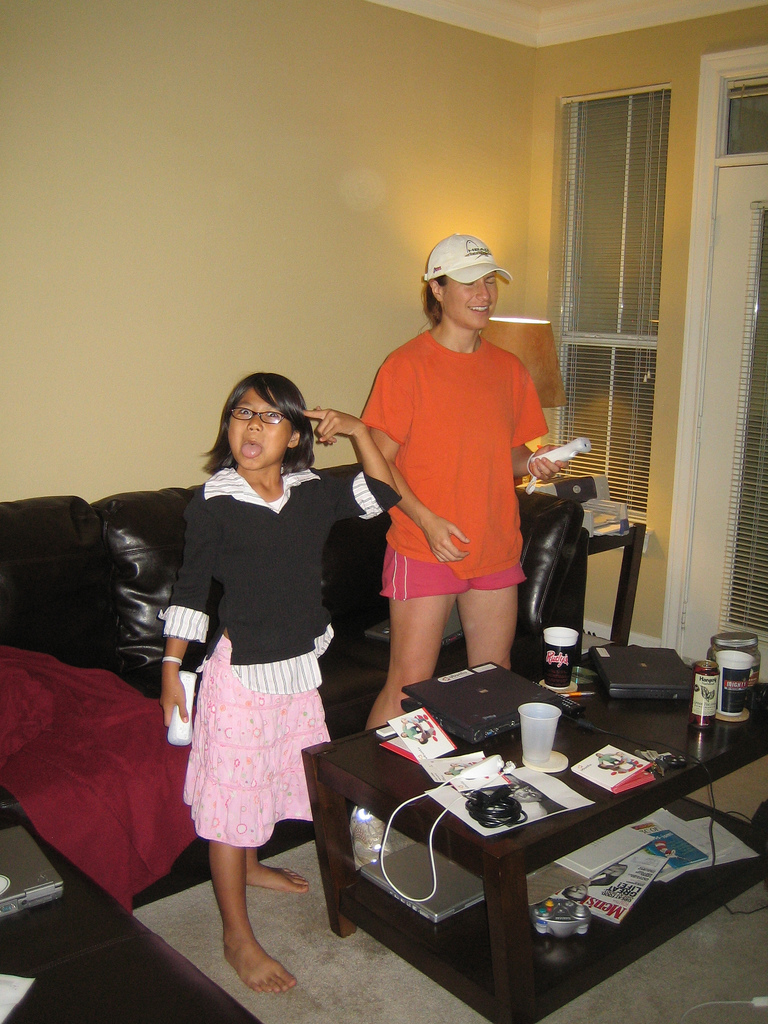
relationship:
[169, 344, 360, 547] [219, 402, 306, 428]
girl wearing glasses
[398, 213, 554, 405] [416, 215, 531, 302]
woman wearing hat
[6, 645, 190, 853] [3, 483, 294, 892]
blanket laying on couch